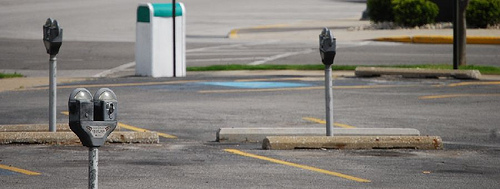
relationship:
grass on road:
[218, 50, 263, 75] [163, 94, 315, 169]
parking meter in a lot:
[62, 85, 118, 187] [1, 5, 494, 186]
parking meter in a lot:
[37, 17, 68, 129] [1, 5, 494, 186]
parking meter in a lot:
[313, 25, 342, 137] [1, 5, 494, 186]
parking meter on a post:
[313, 25, 342, 137] [320, 61, 333, 133]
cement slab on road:
[264, 129, 445, 151] [1, 2, 494, 186]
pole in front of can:
[170, 1, 183, 82] [125, 4, 211, 93]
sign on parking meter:
[85, 122, 111, 140] [62, 85, 118, 187]